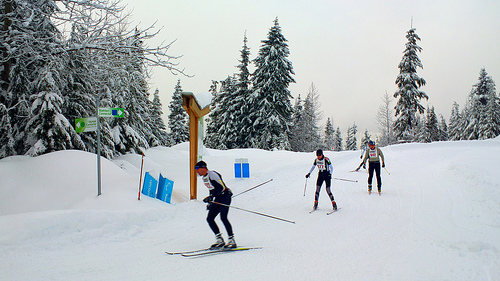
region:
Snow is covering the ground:
[1, 136, 496, 276]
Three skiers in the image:
[154, 124, 409, 267]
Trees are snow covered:
[0, 3, 499, 161]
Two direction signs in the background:
[72, 79, 129, 208]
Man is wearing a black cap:
[191, 151, 214, 179]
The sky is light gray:
[63, 2, 499, 136]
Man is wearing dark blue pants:
[196, 193, 236, 233]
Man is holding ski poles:
[192, 168, 307, 224]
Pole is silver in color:
[87, 88, 107, 196]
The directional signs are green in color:
[68, 94, 130, 140]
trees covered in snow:
[218, 35, 280, 127]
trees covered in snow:
[392, 34, 414, 131]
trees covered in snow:
[232, 50, 296, 158]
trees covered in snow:
[440, 66, 498, 162]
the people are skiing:
[133, 107, 386, 237]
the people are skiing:
[207, 139, 352, 258]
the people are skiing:
[292, 122, 416, 222]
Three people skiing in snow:
[170, 140, 392, 258]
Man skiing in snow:
[163, 160, 299, 258]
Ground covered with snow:
[1, 141, 499, 279]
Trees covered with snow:
[0, 6, 180, 148]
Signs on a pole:
[73, 100, 127, 200]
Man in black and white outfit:
[193, 161, 239, 253]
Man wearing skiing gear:
[302, 148, 346, 218]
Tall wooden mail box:
[180, 93, 210, 198]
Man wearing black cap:
[315, 145, 325, 161]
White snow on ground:
[0, 152, 499, 279]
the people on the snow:
[195, 140, 386, 250]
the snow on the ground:
[1, 134, 498, 279]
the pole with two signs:
[75, 106, 123, 195]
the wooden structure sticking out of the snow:
[179, 91, 210, 200]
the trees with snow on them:
[0, 0, 499, 159]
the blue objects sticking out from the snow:
[143, 158, 248, 202]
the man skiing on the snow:
[164, 160, 295, 257]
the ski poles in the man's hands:
[206, 178, 296, 223]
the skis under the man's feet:
[163, 243, 263, 257]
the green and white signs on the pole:
[74, 106, 124, 133]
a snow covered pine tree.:
[242, 14, 295, 164]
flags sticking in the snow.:
[138, 170, 175, 201]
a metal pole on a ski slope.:
[178, 84, 219, 204]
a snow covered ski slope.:
[0, 132, 499, 279]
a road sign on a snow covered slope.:
[77, 90, 141, 199]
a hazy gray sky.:
[54, 0, 496, 148]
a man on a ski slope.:
[297, 148, 360, 217]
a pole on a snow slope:
[92, 126, 114, 201]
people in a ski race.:
[163, 135, 389, 265]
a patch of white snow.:
[74, 198, 113, 248]